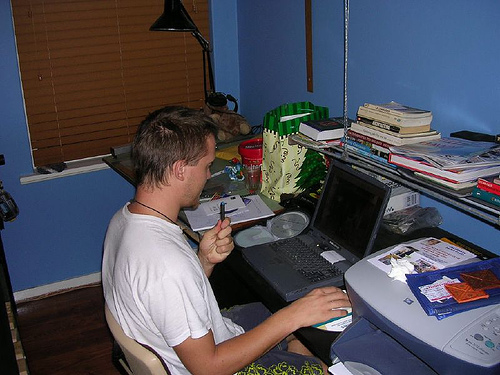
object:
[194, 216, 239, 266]
hand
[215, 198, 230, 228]
pen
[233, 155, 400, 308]
laptop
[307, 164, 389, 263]
screen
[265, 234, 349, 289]
keyboard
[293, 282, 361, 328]
hand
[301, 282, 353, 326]
mouse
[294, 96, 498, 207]
books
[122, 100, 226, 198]
hair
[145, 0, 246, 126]
lamp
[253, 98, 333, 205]
bag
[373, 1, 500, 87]
wall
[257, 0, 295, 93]
wall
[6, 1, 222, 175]
blinds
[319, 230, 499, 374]
printer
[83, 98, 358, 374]
man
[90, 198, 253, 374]
shirt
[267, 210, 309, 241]
cd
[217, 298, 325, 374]
shorts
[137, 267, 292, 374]
arm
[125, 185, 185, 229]
eck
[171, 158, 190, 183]
ear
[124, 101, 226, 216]
head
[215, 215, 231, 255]
figers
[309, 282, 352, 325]
figers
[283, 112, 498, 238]
book shelf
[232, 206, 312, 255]
case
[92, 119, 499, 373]
desk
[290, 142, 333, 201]
christmas tree